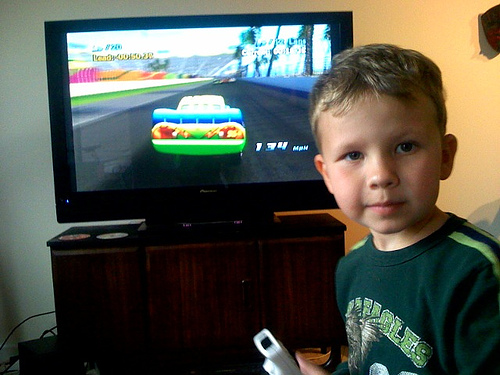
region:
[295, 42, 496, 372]
little boy with blonde hair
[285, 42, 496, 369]
little boy with short hair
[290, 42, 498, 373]
little boy wearing green shirt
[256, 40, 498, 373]
little boy holding white controller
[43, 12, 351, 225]
television behind little boy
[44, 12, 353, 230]
television sitting on wooden surface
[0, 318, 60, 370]
black cords behind television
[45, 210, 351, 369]
brown table underneath television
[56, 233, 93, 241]
game cd sitting on wooden table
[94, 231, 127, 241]
game cd sitting on wooden table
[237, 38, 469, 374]
a little boy with blond hair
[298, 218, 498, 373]
a green shirt with green writing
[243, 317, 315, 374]
a white Wii remote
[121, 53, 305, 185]
a car on the tv screen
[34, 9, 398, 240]
a flat screen tv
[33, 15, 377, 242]
a tv on a stand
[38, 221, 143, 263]
two cd's on the tv stand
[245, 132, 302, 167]
134 on the tv screen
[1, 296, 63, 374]
black cords beside tv stand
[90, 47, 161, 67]
yellow letters and numbers on tv screen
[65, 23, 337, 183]
a video game on the TV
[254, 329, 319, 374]
a remote in the boy's hand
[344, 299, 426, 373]
a design on the tee shirt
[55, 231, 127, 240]
two disks on the table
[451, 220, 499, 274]
stripes on the shirt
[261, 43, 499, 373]
the little boy is playing a game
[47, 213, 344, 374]
a brown TV stand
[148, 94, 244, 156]
a car on the TV screen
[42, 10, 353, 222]
the flat screen TV is on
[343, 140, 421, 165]
the boy has brown eyes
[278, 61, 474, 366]
child wearing green shirt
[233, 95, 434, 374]
child holding white wii controller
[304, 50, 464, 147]
child with dirty blonde hair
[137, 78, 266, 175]
race car on tv screen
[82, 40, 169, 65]
score of game on tv screen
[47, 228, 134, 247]
cds laying under tv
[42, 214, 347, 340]
brown table tv is on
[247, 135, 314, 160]
miles per hour the car in the game is going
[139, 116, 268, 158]
green design on back of car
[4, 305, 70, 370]
black wired beside table that tv is on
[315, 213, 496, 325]
green t shirt on little boy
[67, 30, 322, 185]
video game on tv screen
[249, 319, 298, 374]
whtie wii remote in hand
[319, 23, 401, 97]
blonde hair on little boy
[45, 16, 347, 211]
flat screen tv on stand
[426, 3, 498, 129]
light shining on wall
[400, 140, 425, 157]
blue eye of little boy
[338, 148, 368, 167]
blue eye of little boy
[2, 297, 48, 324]
small black wire by wall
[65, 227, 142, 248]
discs on counter by tv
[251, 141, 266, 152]
A number on the screen.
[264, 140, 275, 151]
A number on the screen.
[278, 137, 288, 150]
A number on the screen.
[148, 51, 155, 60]
A number on the screen.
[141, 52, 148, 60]
A number on the screen.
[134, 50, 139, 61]
A number on the screen.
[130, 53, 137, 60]
A number on the screen.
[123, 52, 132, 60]
A number on the screen.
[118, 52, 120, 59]
A number on the screen.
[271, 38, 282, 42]
A number on the screen.